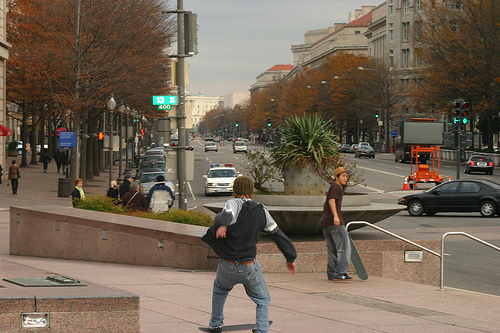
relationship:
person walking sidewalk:
[6, 157, 23, 194] [26, 173, 50, 207]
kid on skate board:
[182, 174, 383, 294] [197, 309, 277, 331]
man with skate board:
[319, 165, 359, 283] [346, 234, 371, 281]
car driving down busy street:
[399, 169, 498, 213] [165, 129, 500, 298]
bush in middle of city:
[270, 102, 362, 194] [240, 8, 498, 152]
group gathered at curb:
[76, 153, 201, 233] [4, 126, 301, 307]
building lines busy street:
[361, 0, 474, 150] [165, 129, 500, 298]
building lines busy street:
[367, 4, 389, 59] [165, 129, 500, 298]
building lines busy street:
[301, 11, 375, 66] [165, 129, 500, 298]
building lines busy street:
[294, 28, 312, 61] [165, 129, 500, 298]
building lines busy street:
[246, 62, 288, 89] [165, 129, 500, 298]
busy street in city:
[161, 118, 495, 290] [1, 0, 497, 320]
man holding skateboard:
[319, 165, 359, 283] [340, 230, 374, 285]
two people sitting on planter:
[125, 182, 178, 213] [62, 188, 252, 260]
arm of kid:
[267, 209, 298, 273] [198, 174, 301, 333]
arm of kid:
[213, 194, 242, 240] [198, 174, 301, 333]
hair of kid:
[233, 174, 250, 195] [198, 174, 301, 333]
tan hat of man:
[332, 165, 349, 177] [319, 165, 359, 283]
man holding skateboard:
[319, 165, 359, 283] [335, 224, 371, 286]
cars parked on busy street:
[129, 134, 171, 216] [165, 129, 500, 298]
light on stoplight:
[461, 117, 469, 124] [446, 93, 470, 131]